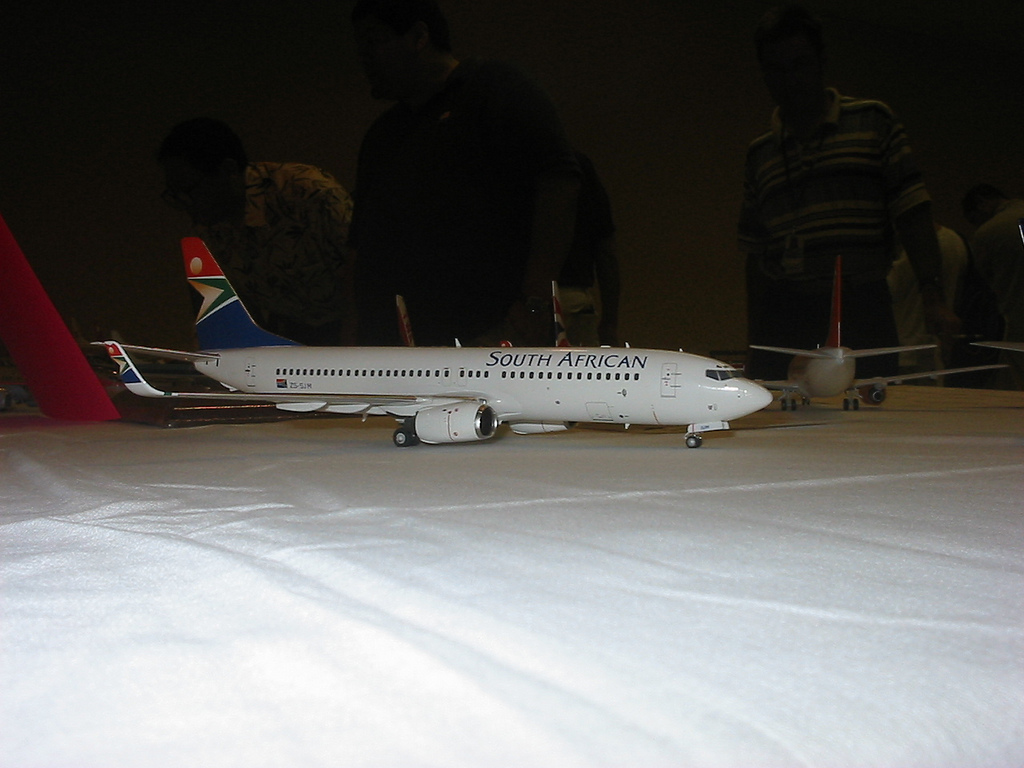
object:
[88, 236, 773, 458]
plane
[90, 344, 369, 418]
wing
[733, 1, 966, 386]
man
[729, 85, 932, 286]
shirt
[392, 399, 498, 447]
engine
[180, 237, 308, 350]
tail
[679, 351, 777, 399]
windshield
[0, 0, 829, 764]
case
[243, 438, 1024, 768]
floor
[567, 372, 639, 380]
window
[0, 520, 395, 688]
cloth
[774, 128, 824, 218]
lanyard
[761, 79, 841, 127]
neck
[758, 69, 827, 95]
glasses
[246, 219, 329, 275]
flower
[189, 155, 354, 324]
shirt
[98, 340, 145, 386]
sign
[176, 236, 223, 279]
tip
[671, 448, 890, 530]
pavement